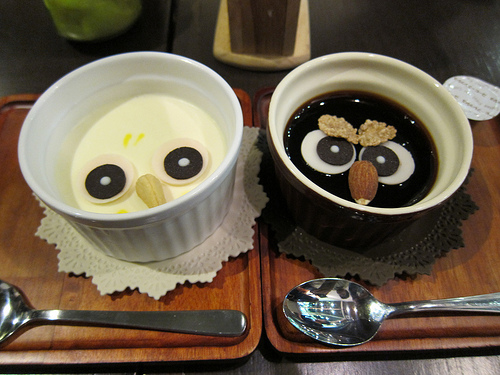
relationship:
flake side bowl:
[354, 115, 401, 148] [266, 52, 474, 216]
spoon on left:
[9, 278, 266, 345] [5, 45, 58, 373]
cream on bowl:
[47, 90, 231, 220] [17, 50, 244, 263]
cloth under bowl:
[256, 127, 481, 287] [266, 52, 474, 216]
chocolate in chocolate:
[282, 90, 438, 208] [282, 90, 438, 208]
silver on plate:
[281, 277, 500, 348] [262, 70, 498, 362]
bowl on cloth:
[266, 52, 474, 216] [250, 40, 484, 286]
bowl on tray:
[324, 57, 381, 88] [451, 213, 483, 265]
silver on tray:
[281, 277, 500, 348] [451, 213, 483, 265]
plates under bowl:
[0, 88, 260, 364] [17, 50, 244, 264]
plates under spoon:
[0, 88, 260, 364] [0, 281, 249, 341]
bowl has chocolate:
[266, 52, 474, 216] [339, 89, 391, 114]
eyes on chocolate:
[300, 126, 415, 186] [282, 90, 438, 208]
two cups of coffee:
[15, 48, 475, 265] [358, 92, 379, 112]